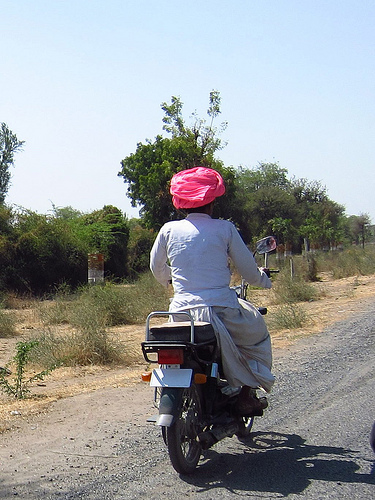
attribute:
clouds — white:
[212, 93, 359, 170]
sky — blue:
[0, 0, 373, 146]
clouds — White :
[0, 0, 373, 225]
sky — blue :
[0, 1, 373, 226]